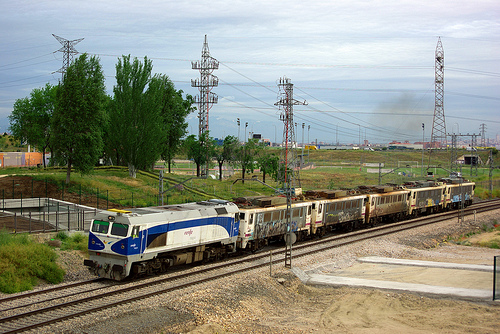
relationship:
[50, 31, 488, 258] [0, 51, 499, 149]
poles with wires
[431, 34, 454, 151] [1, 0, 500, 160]
utility tower in background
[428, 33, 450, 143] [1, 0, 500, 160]
tower in background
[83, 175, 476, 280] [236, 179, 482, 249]
train has train cars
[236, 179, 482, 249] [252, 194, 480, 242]
train cars have graffiti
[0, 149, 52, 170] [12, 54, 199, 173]
building by trees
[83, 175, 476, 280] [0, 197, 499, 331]
train on tracks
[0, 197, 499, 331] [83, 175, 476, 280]
tracks have train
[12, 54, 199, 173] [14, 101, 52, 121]
trees have leaves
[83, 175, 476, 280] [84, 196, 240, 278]
train has engine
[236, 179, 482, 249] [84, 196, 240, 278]
train cars behind engine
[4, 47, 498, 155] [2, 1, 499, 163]
power lines in air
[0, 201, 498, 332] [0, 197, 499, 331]
gravel around tracks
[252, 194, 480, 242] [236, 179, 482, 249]
graffiti on train cars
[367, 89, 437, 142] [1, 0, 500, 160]
smoke in background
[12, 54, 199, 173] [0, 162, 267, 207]
trees on hill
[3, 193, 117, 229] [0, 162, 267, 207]
tunnel by hill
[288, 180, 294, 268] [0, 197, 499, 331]
pole by tracks